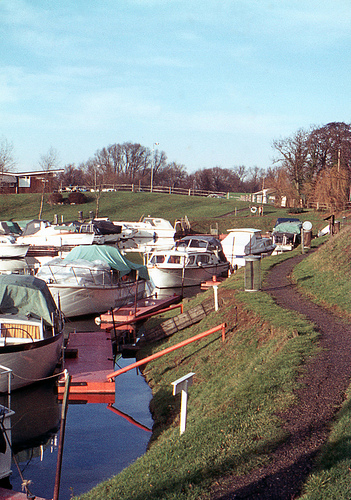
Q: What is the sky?
A: Blue with some faint white clouds.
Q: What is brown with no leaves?
A: Trees.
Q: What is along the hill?
A: A path.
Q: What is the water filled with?
A: Boats.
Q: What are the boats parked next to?
A: Docks.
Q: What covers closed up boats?
A: Tarps.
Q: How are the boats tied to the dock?
A: Ropes.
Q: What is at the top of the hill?
A: Building.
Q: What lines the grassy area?
A: Fence.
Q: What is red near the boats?
A: Docks.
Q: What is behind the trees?
A: Sky.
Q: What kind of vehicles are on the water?
A: Boats.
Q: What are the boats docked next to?
A: Raised green hills.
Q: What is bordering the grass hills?
A: Fence.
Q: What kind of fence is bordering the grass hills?
A: Wooden fence.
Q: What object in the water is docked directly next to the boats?
A: Orange metal dock.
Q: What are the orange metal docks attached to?
A: Nearby grass covered ground.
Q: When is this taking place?
A: Daytime.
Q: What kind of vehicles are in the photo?
A: Boats.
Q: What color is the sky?
A: Blue.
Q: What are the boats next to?
A: Grass incline.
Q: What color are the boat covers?
A: Light green.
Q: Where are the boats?
A: Body of water.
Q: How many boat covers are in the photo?
A: Six.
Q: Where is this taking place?
A: At a riverside dock.